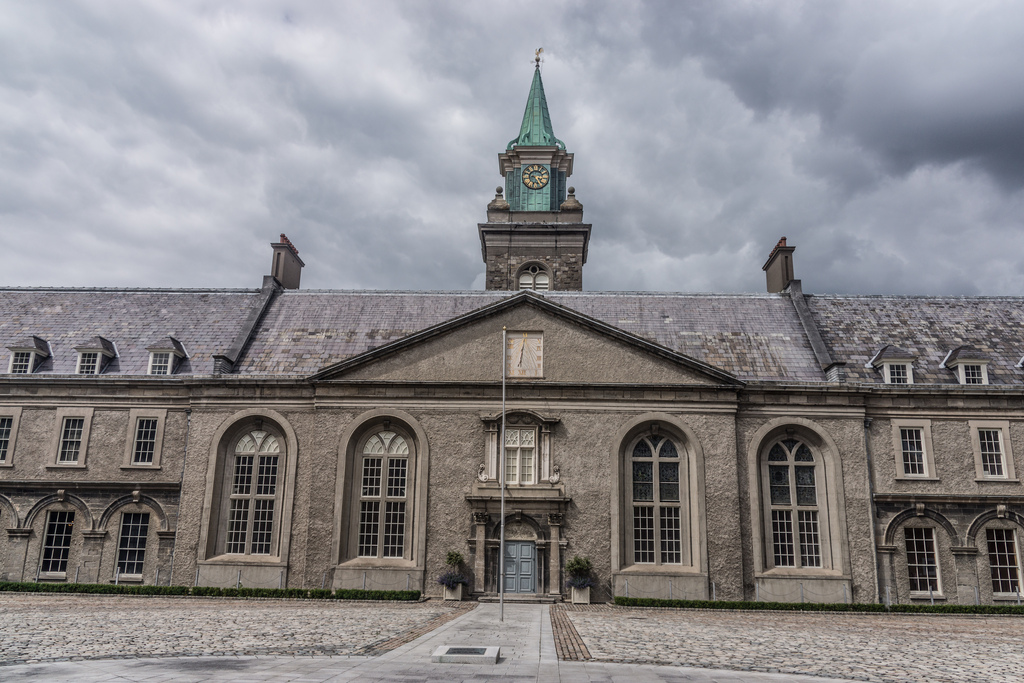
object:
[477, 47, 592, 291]
steeple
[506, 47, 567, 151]
top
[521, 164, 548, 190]
clock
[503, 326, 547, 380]
clock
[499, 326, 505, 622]
pole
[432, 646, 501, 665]
drain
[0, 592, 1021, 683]
sidewalk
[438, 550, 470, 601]
pot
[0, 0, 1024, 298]
clouds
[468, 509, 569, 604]
door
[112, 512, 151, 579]
window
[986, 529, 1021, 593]
window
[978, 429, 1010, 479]
window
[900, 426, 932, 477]
window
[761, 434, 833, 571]
window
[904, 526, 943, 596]
window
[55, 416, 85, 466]
window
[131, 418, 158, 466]
window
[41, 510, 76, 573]
window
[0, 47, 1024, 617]
building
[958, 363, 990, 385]
window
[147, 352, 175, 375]
window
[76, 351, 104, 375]
window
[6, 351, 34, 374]
window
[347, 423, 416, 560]
window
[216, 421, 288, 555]
window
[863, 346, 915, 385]
window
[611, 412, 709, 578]
window